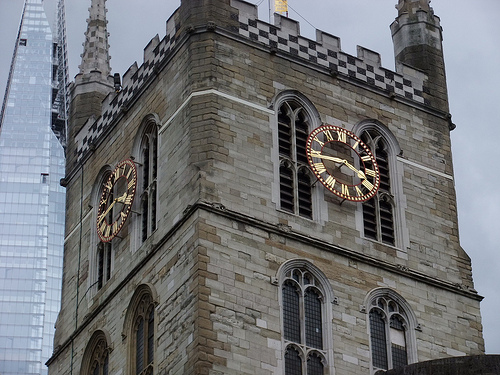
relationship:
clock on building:
[76, 120, 411, 243] [42, 2, 496, 369]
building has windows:
[42, 2, 496, 369] [82, 120, 418, 365]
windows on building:
[82, 120, 418, 365] [42, 2, 496, 369]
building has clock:
[42, 2, 496, 369] [76, 120, 411, 243]